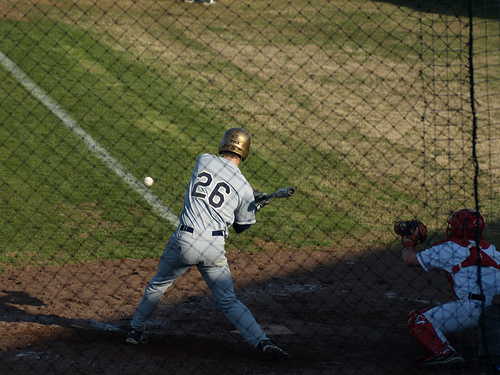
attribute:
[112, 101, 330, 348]
player — not in white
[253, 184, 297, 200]
bat — black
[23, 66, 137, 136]
color — green 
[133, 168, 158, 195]
ball — red, white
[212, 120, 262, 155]
helmet — gold 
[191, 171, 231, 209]
number — 26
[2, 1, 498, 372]
netting — protective